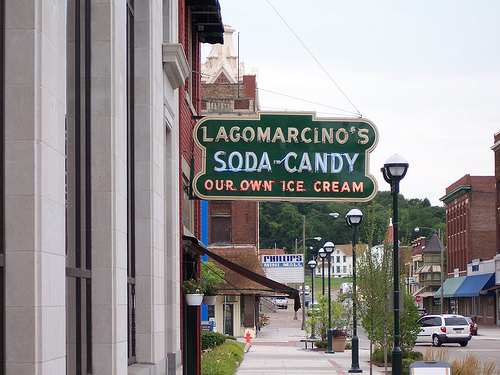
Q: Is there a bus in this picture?
A: No, there are no buses.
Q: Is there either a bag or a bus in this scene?
A: No, there are no buses or bags.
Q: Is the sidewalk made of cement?
A: Yes, the sidewalk is made of cement.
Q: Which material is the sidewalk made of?
A: The sidewalk is made of cement.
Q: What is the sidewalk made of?
A: The sidewalk is made of concrete.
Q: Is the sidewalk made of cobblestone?
A: No, the sidewalk is made of cement.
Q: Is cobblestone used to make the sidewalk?
A: No, the sidewalk is made of cement.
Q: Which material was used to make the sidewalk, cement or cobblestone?
A: The sidewalk is made of cement.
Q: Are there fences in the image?
A: No, there are no fences.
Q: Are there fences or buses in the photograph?
A: No, there are no fences or buses.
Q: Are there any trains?
A: No, there are no trains.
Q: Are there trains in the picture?
A: No, there are no trains.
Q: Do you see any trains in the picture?
A: No, there are no trains.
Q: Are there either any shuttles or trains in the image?
A: No, there are no trains or shuttles.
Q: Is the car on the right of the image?
A: Yes, the car is on the right of the image.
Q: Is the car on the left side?
A: No, the car is on the right of the image.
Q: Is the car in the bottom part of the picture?
A: Yes, the car is in the bottom of the image.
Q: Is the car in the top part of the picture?
A: No, the car is in the bottom of the image.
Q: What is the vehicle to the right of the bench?
A: The vehicle is a car.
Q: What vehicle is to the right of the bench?
A: The vehicle is a car.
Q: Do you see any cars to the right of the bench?
A: Yes, there is a car to the right of the bench.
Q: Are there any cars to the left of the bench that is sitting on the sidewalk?
A: No, the car is to the right of the bench.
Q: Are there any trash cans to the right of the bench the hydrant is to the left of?
A: No, there is a car to the right of the bench.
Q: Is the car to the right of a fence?
A: No, the car is to the right of the bench.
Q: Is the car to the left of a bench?
A: No, the car is to the right of a bench.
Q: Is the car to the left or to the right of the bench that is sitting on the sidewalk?
A: The car is to the right of the bench.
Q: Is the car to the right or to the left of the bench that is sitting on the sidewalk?
A: The car is to the right of the bench.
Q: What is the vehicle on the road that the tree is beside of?
A: The vehicle is a car.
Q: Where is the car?
A: The car is on the road.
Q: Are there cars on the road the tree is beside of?
A: Yes, there is a car on the road.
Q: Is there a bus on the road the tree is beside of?
A: No, there is a car on the road.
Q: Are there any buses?
A: No, there are no buses.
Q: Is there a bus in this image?
A: No, there are no buses.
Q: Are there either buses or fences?
A: No, there are no buses or fences.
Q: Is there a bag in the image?
A: No, there are no bags.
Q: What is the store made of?
A: The store is made of brick.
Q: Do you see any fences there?
A: No, there are no fences.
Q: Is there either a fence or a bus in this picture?
A: No, there are no fences or buses.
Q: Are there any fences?
A: No, there are no fences.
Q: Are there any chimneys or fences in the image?
A: No, there are no fences or chimneys.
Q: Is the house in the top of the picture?
A: No, the house is in the bottom of the image.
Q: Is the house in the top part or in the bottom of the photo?
A: The house is in the bottom of the image.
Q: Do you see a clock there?
A: No, there are no clocks.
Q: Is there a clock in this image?
A: No, there are no clocks.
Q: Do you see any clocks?
A: No, there are no clocks.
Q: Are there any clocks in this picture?
A: No, there are no clocks.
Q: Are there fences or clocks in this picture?
A: No, there are no clocks or fences.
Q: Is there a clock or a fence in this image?
A: No, there are no clocks or fences.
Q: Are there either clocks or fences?
A: No, there are no clocks or fences.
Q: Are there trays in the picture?
A: No, there are no trays.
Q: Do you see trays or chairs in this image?
A: No, there are no trays or chairs.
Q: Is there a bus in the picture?
A: No, there are no buses.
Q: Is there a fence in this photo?
A: No, there are no fences.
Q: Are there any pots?
A: Yes, there is a pot.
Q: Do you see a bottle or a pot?
A: Yes, there is a pot.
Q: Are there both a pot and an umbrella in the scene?
A: No, there is a pot but no umbrellas.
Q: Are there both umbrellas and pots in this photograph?
A: No, there is a pot but no umbrellas.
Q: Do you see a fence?
A: No, there are no fences.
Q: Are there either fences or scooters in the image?
A: No, there are no fences or scooters.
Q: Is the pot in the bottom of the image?
A: Yes, the pot is in the bottom of the image.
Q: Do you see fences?
A: No, there are no fences.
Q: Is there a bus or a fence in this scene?
A: No, there are no fences or buses.